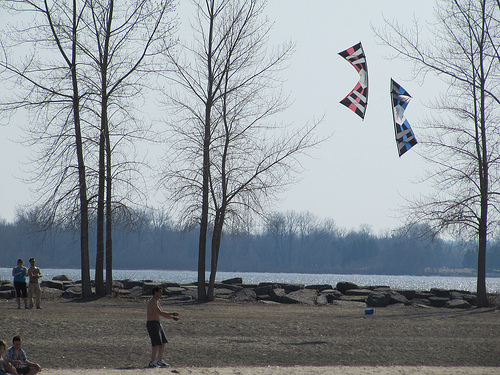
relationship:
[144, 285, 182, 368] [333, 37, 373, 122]
man flying kite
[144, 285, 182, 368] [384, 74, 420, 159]
man flying kite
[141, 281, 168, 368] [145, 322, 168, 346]
man wearing shorts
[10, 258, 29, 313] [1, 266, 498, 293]
person standing by lake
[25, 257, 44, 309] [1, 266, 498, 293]
person standing by lake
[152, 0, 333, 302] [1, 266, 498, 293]
tree next to lake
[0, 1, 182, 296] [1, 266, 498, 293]
tree next to lake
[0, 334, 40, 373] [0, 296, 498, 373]
children sitting on ground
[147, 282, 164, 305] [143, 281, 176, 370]
head of man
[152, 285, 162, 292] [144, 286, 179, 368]
hair of man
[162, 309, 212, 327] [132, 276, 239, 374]
arm of man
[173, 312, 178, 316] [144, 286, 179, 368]
hand of man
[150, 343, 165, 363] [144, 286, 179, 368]
legs of man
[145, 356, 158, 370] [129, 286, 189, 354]
foot of man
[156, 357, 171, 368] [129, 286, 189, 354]
foot of man